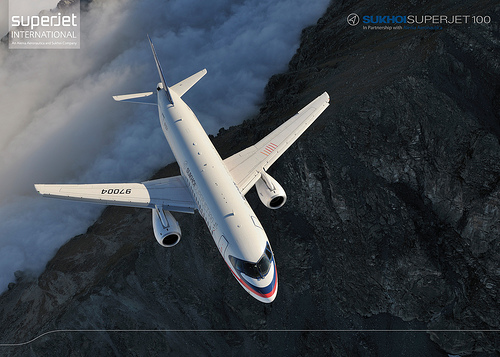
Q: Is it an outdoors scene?
A: Yes, it is outdoors.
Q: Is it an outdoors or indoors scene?
A: It is outdoors.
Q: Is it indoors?
A: No, it is outdoors.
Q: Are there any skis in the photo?
A: No, there are no skis.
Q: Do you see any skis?
A: No, there are no skis.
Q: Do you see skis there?
A: No, there are no skis.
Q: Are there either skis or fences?
A: No, there are no skis or fences.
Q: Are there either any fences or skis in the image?
A: No, there are no skis or fences.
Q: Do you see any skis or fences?
A: No, there are no skis or fences.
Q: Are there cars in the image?
A: No, there are no cars.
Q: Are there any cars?
A: No, there are no cars.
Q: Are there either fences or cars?
A: No, there are no cars or fences.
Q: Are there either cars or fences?
A: No, there are no cars or fences.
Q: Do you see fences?
A: No, there are no fences.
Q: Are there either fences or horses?
A: No, there are no fences or horses.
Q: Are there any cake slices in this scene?
A: No, there are no cake slices.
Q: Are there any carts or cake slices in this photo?
A: No, there are no cake slices or carts.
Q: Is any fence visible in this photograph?
A: No, there are no fences.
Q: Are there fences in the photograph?
A: No, there are no fences.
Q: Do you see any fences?
A: No, there are no fences.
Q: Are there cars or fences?
A: No, there are no fences or cars.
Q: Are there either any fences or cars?
A: No, there are no fences or cars.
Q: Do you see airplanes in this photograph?
A: Yes, there is an airplane.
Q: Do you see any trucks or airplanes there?
A: Yes, there is an airplane.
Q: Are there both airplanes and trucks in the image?
A: No, there is an airplane but no trucks.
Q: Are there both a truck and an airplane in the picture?
A: No, there is an airplane but no trucks.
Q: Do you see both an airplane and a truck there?
A: No, there is an airplane but no trucks.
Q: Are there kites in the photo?
A: No, there are no kites.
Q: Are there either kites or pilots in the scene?
A: No, there are no kites or pilots.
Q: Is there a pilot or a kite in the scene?
A: No, there are no kites or pilots.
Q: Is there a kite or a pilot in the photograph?
A: No, there are no kites or pilots.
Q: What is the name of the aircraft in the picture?
A: The aircraft is an airplane.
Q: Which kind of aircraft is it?
A: The aircraft is an airplane.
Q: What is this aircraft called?
A: That is an airplane.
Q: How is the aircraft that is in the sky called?
A: The aircraft is an airplane.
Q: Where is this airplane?
A: The airplane is in the sky.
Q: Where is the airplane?
A: The airplane is in the sky.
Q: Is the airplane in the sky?
A: Yes, the airplane is in the sky.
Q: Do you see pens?
A: No, there are no pens.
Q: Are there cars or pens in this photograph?
A: No, there are no pens or cars.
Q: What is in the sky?
A: The clouds are in the sky.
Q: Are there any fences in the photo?
A: No, there are no fences.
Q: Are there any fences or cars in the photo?
A: No, there are no fences or cars.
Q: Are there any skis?
A: No, there are no skis.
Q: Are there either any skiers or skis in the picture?
A: No, there are no skis or skiers.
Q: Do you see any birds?
A: No, there are no birds.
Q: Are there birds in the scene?
A: No, there are no birds.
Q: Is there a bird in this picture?
A: No, there are no birds.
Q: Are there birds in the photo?
A: No, there are no birds.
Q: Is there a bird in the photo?
A: No, there are no birds.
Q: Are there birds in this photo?
A: No, there are no birds.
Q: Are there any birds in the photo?
A: No, there are no birds.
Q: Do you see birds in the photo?
A: No, there are no birds.